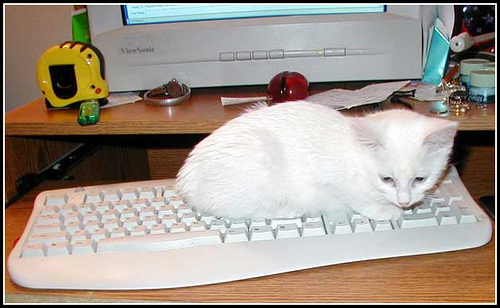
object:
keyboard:
[7, 164, 493, 292]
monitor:
[88, 0, 423, 93]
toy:
[35, 41, 110, 107]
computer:
[84, 4, 438, 93]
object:
[220, 96, 266, 106]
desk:
[0, 45, 497, 136]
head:
[350, 109, 460, 208]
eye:
[415, 175, 426, 182]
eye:
[379, 175, 395, 184]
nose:
[398, 201, 411, 206]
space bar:
[96, 231, 223, 253]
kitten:
[173, 100, 460, 222]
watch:
[143, 78, 191, 107]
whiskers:
[375, 197, 390, 202]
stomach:
[287, 193, 321, 219]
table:
[3, 208, 500, 304]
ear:
[349, 119, 390, 148]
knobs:
[268, 49, 284, 59]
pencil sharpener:
[428, 100, 450, 116]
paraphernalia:
[35, 40, 111, 109]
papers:
[304, 80, 412, 111]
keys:
[119, 208, 139, 218]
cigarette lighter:
[77, 99, 100, 126]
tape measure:
[35, 40, 110, 110]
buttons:
[220, 52, 235, 61]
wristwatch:
[449, 90, 470, 104]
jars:
[467, 70, 494, 105]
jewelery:
[448, 103, 472, 114]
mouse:
[267, 70, 309, 103]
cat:
[174, 99, 461, 221]